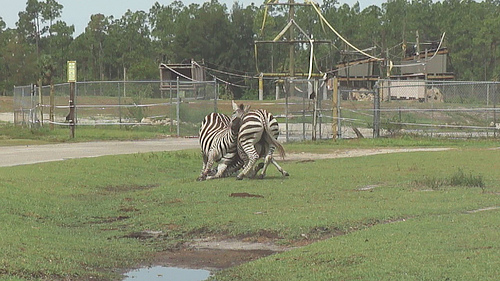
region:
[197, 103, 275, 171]
two zebras rubbing against each other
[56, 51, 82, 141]
sign on a metal post beside road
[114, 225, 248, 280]
hole with water in the grass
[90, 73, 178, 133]
chain link fence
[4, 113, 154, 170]
road with grass on each side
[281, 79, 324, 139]
open gate on the road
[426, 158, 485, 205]
weeds growing in the grass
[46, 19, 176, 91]
trees beyond the fence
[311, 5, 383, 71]
yellow cable hanging down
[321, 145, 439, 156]
patch of dirt in the grass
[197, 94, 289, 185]
two zebras leaning on each other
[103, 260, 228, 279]
small water puddle in the ground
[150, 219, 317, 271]
patch of dirt in the ground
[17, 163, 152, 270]
green grassy lawn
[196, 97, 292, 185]
two black and white zebras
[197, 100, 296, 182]
zebras on the grass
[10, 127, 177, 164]
grey concrete walkway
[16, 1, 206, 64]
trees with green leaves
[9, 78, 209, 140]
metal grey fence around grass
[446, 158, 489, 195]
patch of tall green grass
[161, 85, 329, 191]
two zebras in a field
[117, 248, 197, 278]
the puddle of water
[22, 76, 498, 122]
the chain link fence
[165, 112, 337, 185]
the zebras are charging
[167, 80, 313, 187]
the zebras are striped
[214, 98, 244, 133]
the head of the zebra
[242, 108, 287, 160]
the rear end of the zebra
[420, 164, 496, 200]
a patch of grass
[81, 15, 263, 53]
trees with green leaves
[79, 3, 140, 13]
the clear blue sky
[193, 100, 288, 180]
Two zebras fighting each other.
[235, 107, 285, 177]
The back of a fat zebra.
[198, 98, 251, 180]
A zebra is facing forward.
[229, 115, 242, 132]
The black nose and mouth of a zebra.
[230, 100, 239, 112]
The ear of an adult zebra.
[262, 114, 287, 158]
The tail of a fat zebra.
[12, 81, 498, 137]
A large amount of fences connected to each other.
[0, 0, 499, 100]
A large number of trees are behind the facility.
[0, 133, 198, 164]
A concrete road is leading to the facility.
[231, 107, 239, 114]
The left eye of a zebra.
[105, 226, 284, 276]
the water is on the ground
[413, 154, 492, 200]
the patch of grass is long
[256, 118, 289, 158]
the zebra has a tail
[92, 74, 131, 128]
the fence is metal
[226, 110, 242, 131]
the zebra has a nose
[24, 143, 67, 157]
the road is gray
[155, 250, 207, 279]
the water is dark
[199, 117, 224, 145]
the zebra has stripes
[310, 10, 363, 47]
the line is thick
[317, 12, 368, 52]
the line is yellow